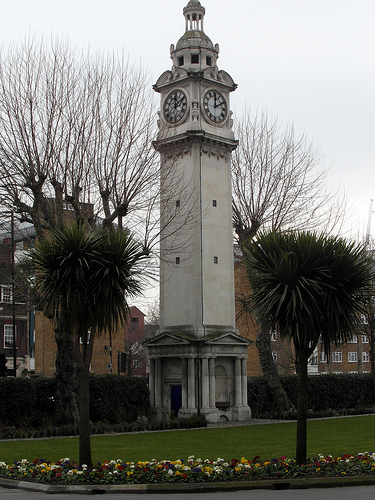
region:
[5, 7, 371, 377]
a cloudy day in the tropics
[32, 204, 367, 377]
two palm trees in garden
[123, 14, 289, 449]
the clock tower is white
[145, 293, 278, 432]
the base of the clock tower is greek styled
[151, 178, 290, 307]
there are two windows on each side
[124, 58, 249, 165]
the clock face is white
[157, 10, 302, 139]
a cupola on the top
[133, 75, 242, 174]
the numbers are black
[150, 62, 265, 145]
the numbers are roman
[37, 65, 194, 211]
the tree branches are bare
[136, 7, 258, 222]
A clock tower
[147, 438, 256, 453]
Green color grass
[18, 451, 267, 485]
Variety of flowers near the lawn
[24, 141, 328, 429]
Trees with branches near the tower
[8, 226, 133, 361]
Buildings near the tower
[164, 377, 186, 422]
Entrance of the tower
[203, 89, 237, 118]
Roman letter clock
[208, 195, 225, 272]
Windows of the tower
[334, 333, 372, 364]
Lot of windows in the building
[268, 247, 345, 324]
Green color leaves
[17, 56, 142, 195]
the tree is dry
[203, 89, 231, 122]
the tower has a clock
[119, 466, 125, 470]
the flower is red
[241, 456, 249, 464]
the flower is yellow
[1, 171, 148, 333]
the house is on the backgroumd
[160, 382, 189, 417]
the tower has an etrance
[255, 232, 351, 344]
the tree is green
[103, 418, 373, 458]
the field is green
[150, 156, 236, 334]
the tower is green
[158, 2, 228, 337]
the tower has two clocks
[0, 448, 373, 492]
THESE ARE FLOWERS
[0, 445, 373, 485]
THE FLOWERS ARE COLORFUL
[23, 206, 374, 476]
THESE ARE TREES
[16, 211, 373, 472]
THE TREES ARE PALMS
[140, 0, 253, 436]
THIS IS A TOWER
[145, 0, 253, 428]
THE TOWER IS TALL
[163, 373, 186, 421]
THIS IS A DOOR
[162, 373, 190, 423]
THE DOOR IS ON THE TOWER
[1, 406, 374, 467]
THIS IS LUSH GREEN GRASS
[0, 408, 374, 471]
THE LUSH GREEN GRASS IS COVERING THE GROUND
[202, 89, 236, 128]
clock on right side of tower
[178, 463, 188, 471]
white flower in flower bed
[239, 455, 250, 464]
yellow flower in flower bed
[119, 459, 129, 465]
purple flower in flower bed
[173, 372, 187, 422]
blue door of clock tower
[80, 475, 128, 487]
green leaves of flowers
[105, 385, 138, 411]
green shrubs in background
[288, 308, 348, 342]
spiky green leaves on tree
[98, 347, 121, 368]
maroon brick building in background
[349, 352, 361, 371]
white window in brick building